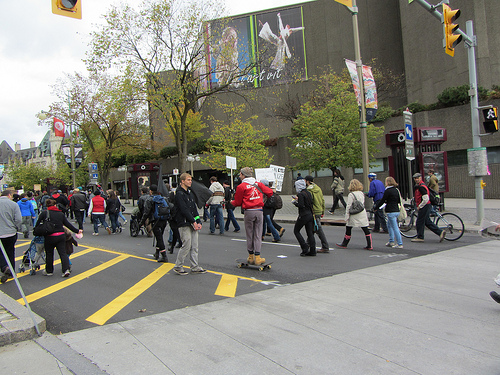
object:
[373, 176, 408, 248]
pedestrian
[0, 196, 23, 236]
jacket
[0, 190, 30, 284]
human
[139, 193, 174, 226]
jacket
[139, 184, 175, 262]
human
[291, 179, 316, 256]
pedestrian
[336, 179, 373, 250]
person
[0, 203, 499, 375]
street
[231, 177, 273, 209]
jacket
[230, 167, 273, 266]
man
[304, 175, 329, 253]
pedestrian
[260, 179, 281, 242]
pedestrian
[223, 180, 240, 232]
pedestrian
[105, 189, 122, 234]
pedestrian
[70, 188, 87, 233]
pedestrian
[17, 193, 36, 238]
pedestrian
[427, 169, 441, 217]
pedestrian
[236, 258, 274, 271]
skateboard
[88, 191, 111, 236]
person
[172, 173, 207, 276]
person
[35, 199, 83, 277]
person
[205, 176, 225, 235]
human